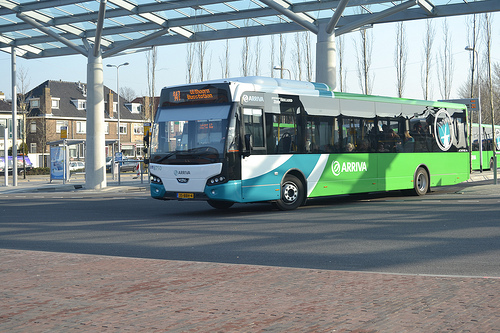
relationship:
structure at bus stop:
[84, 35, 112, 186] [47, 136, 118, 183]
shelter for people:
[0, 8, 484, 227] [269, 127, 305, 254]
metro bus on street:
[141, 81, 473, 211] [1, 185, 492, 325]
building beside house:
[0, 86, 23, 183] [15, 79, 148, 170]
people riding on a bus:
[251, 122, 414, 149] [137, 72, 478, 212]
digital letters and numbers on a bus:
[158, 89, 220, 103] [136, 100, 476, 220]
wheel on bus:
[281, 168, 311, 217] [137, 72, 478, 212]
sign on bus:
[152, 79, 233, 104] [137, 72, 478, 212]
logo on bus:
[335, 154, 376, 175] [137, 72, 478, 212]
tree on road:
[462, 57, 498, 120] [6, 186, 498, 324]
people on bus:
[239, 119, 428, 148] [137, 72, 478, 212]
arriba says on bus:
[335, 157, 373, 173] [142, 61, 476, 215]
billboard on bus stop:
[44, 139, 67, 179] [42, 135, 122, 178]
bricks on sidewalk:
[319, 301, 355, 317] [1, 244, 499, 331]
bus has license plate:
[137, 72, 478, 212] [168, 188, 197, 202]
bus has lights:
[137, 72, 478, 212] [146, 172, 224, 188]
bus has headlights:
[137, 72, 478, 212] [142, 172, 225, 186]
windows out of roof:
[73, 97, 89, 113] [22, 79, 127, 117]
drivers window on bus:
[239, 100, 271, 158] [136, 79, 490, 209]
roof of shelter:
[0, 0, 492, 59] [0, 1, 500, 249]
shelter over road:
[0, 1, 500, 249] [4, 164, 495, 283]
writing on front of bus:
[169, 166, 193, 183] [145, 75, 474, 212]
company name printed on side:
[329, 152, 367, 182] [245, 111, 466, 198]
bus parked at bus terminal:
[145, 75, 474, 212] [3, 2, 495, 316]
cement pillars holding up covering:
[76, 40, 108, 190] [14, 0, 283, 80]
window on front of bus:
[146, 96, 231, 157] [136, 79, 490, 209]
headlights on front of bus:
[146, 169, 160, 189] [137, 72, 478, 212]